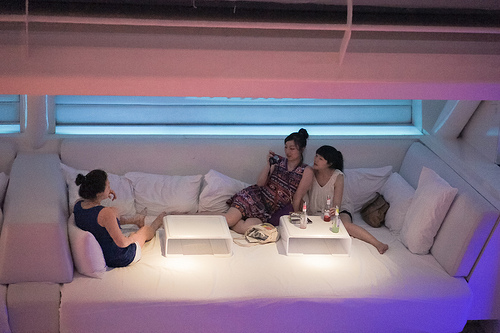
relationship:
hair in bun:
[72, 167, 108, 204] [72, 175, 85, 188]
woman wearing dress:
[302, 148, 392, 255] [304, 169, 344, 216]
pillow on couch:
[67, 212, 105, 276] [4, 135, 492, 330]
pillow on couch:
[67, 161, 141, 221] [4, 135, 492, 330]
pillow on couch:
[125, 173, 200, 215] [4, 135, 492, 330]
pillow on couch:
[200, 174, 250, 217] [4, 135, 492, 330]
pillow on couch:
[339, 166, 388, 211] [4, 135, 492, 330]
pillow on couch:
[378, 170, 408, 227] [4, 135, 492, 330]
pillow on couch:
[398, 163, 448, 254] [4, 135, 492, 330]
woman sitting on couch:
[66, 161, 174, 275] [4, 135, 492, 330]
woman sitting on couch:
[219, 124, 317, 244] [4, 135, 492, 330]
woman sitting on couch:
[302, 148, 392, 255] [4, 135, 492, 330]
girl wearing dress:
[63, 161, 164, 272] [73, 201, 143, 265]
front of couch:
[158, 265, 379, 312] [4, 135, 492, 330]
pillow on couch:
[398, 163, 459, 254] [4, 135, 492, 330]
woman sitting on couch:
[66, 161, 174, 275] [34, 138, 479, 331]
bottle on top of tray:
[299, 201, 308, 230] [280, 209, 351, 255]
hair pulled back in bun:
[72, 167, 110, 201] [69, 169, 88, 188]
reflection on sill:
[57, 121, 420, 141] [54, 119, 426, 140]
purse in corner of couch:
[354, 185, 403, 234] [34, 138, 479, 331]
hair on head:
[312, 143, 355, 169] [315, 144, 340, 177]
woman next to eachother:
[219, 124, 317, 244] [218, 123, 386, 260]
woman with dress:
[302, 148, 392, 255] [304, 168, 344, 216]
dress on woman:
[218, 149, 313, 229] [219, 124, 317, 244]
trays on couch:
[154, 204, 354, 261] [4, 135, 492, 330]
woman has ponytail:
[219, 124, 317, 244] [294, 126, 314, 143]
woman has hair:
[66, 161, 174, 275] [72, 162, 106, 205]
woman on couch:
[66, 161, 174, 275] [34, 138, 479, 331]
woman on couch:
[219, 124, 317, 244] [34, 138, 479, 331]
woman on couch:
[302, 148, 392, 255] [34, 138, 479, 331]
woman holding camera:
[219, 120, 317, 244] [268, 155, 298, 190]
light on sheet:
[133, 245, 358, 279] [61, 225, 461, 328]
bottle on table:
[291, 190, 319, 236] [272, 210, 350, 260]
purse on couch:
[362, 195, 391, 228] [4, 135, 492, 330]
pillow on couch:
[114, 170, 210, 231] [4, 135, 492, 330]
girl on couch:
[289, 141, 394, 257] [4, 135, 492, 330]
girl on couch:
[223, 124, 321, 244] [4, 135, 492, 330]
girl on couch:
[63, 161, 164, 272] [4, 135, 492, 330]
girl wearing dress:
[63, 161, 164, 272] [75, 196, 139, 267]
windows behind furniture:
[0, 103, 429, 145] [3, 135, 493, 331]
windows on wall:
[0, 103, 429, 145] [2, 101, 489, 148]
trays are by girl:
[160, 210, 235, 258] [63, 161, 164, 272]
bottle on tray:
[283, 200, 346, 236] [272, 205, 351, 257]